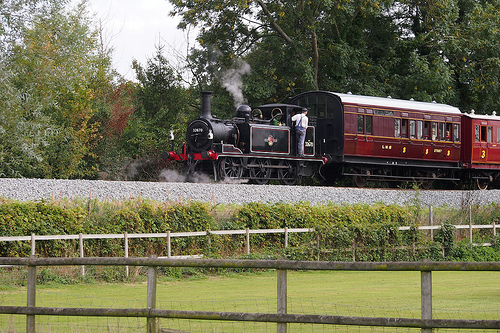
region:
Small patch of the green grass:
[320, 286, 342, 303]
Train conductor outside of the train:
[294, 106, 309, 153]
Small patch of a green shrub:
[139, 210, 163, 228]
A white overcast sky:
[132, 13, 152, 28]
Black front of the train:
[186, 120, 213, 155]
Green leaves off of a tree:
[420, 68, 442, 85]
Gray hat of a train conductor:
[301, 106, 308, 111]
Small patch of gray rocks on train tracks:
[103, 181, 123, 196]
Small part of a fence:
[418, 260, 434, 322]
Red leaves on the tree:
[118, 110, 128, 128]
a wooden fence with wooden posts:
[0, 198, 496, 325]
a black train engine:
[170, 101, 321, 176]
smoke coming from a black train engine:
[168, 42, 320, 182]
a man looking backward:
[291, 106, 311, 153]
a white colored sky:
[6, 0, 474, 92]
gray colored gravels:
[1, 178, 498, 204]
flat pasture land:
[1, 270, 498, 330]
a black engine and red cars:
[166, 88, 499, 185]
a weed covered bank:
[1, 201, 498, 283]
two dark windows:
[350, 113, 377, 133]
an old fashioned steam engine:
[160, 80, 322, 182]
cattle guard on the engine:
[150, 159, 216, 181]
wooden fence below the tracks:
[0, 257, 495, 330]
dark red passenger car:
[298, 89, 465, 188]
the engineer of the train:
[288, 106, 313, 154]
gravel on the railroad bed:
[0, 180, 495, 210]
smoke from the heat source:
[217, 55, 288, 120]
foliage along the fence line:
[0, 201, 498, 282]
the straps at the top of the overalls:
[296, 114, 305, 126]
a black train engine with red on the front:
[165, 92, 329, 182]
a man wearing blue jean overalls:
[289, 108, 309, 157]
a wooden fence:
[1, 203, 499, 330]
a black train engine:
[166, 90, 323, 182]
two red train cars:
[288, 92, 498, 188]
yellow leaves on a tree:
[69, 83, 101, 153]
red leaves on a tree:
[103, 80, 133, 135]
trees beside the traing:
[2, 0, 499, 180]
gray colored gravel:
[0, 175, 498, 206]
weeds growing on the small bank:
[1, 206, 498, 263]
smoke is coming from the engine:
[168, 59, 328, 183]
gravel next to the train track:
[140, 183, 209, 202]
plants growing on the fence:
[297, 209, 366, 247]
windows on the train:
[356, 106, 379, 141]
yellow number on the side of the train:
[400, 144, 410, 158]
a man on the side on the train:
[294, 98, 311, 155]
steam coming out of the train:
[219, 65, 250, 109]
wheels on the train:
[217, 156, 259, 183]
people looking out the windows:
[439, 119, 453, 143]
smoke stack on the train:
[199, 87, 218, 122]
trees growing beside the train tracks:
[85, 101, 149, 178]